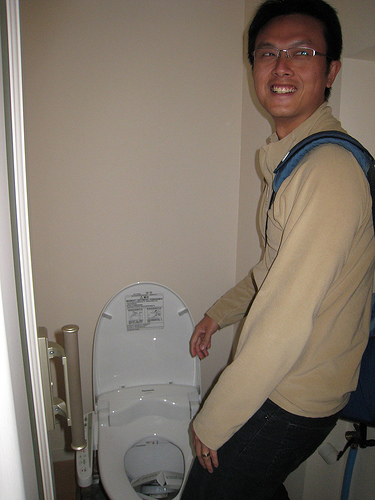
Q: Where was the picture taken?
A: A bathroom.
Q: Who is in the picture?
A: A man.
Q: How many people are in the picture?
A: One.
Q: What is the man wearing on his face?
A: Glasses.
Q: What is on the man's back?
A: Backpack.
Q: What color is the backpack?
A: Blue.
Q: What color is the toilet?
A: White.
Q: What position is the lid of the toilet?
A: Up.